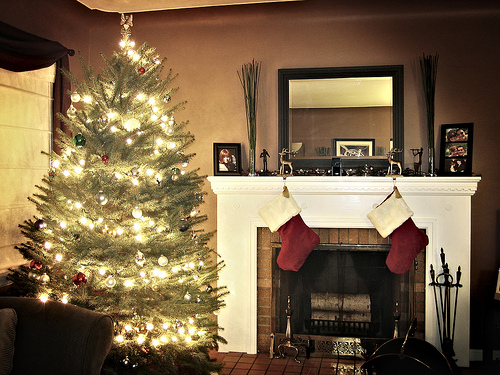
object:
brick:
[212, 349, 338, 374]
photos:
[439, 122, 474, 177]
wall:
[67, 9, 499, 175]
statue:
[259, 149, 270, 177]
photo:
[211, 142, 242, 175]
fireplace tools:
[428, 247, 463, 367]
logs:
[311, 292, 372, 328]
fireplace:
[204, 175, 482, 367]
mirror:
[287, 75, 396, 161]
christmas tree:
[6, 7, 230, 375]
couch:
[0, 298, 115, 375]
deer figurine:
[383, 147, 404, 177]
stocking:
[366, 185, 428, 275]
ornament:
[72, 272, 88, 286]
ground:
[360, 50, 400, 90]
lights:
[37, 39, 214, 350]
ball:
[158, 253, 169, 266]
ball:
[138, 67, 145, 75]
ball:
[72, 134, 87, 148]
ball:
[72, 272, 87, 288]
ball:
[99, 196, 108, 206]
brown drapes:
[0, 61, 57, 287]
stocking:
[258, 189, 320, 272]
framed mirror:
[276, 64, 404, 173]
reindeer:
[276, 147, 296, 177]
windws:
[0, 72, 53, 291]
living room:
[0, 0, 500, 374]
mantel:
[206, 175, 480, 196]